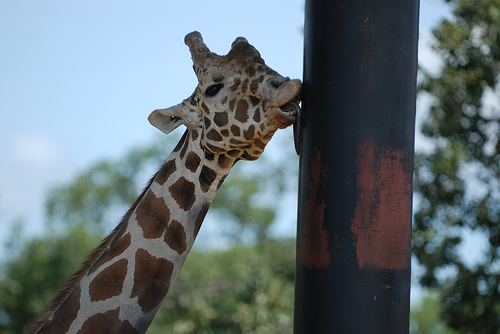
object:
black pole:
[291, 0, 420, 333]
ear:
[146, 95, 201, 136]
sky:
[0, 4, 497, 266]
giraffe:
[21, 30, 305, 334]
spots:
[301, 138, 416, 281]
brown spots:
[128, 248, 175, 312]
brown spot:
[167, 176, 199, 212]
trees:
[5, 125, 290, 332]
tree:
[419, 5, 498, 332]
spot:
[153, 206, 185, 266]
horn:
[184, 27, 214, 70]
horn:
[230, 35, 252, 47]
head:
[146, 28, 303, 160]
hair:
[25, 164, 163, 334]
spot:
[134, 190, 169, 243]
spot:
[154, 157, 177, 185]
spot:
[84, 257, 130, 305]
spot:
[182, 148, 201, 172]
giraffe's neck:
[22, 130, 249, 331]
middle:
[118, 220, 177, 258]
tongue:
[288, 101, 302, 155]